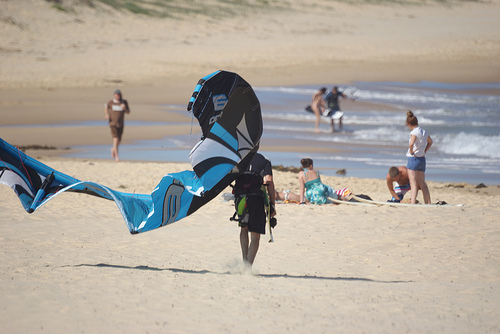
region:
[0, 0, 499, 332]
light sandy shore side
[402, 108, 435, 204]
woman with a bun hairstyle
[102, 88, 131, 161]
man jogging wearing all brown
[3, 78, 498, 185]
water coming into the shore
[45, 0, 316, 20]
grass patch on the sand dune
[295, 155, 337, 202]
woman wearing a green and white flowery dress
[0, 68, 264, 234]
large blue and black para sail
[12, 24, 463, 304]
this is on a beach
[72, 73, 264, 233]
this is a kite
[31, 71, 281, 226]
the kite is big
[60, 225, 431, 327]
this is a shadow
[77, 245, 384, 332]
the beach is sandy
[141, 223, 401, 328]
the man is walking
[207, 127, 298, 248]
the man is wearing black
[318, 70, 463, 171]
this is the ocean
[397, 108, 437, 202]
a cute girl on the beach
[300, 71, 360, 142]
a couple of people by the shore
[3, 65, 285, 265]
a man carries a large windsail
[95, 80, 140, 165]
a man in a brown shirt jogs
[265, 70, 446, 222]
people gather on a sandy beach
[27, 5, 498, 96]
big dunes above a shore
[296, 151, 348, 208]
a girl sitting on a towel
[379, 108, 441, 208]
a couple of people working on something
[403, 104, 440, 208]
a pretty woman in blue shorts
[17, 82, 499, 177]
ocean water on shore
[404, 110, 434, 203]
woman with hands on hips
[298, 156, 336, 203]
woman sitting on beach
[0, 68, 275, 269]
walking man carrying parasail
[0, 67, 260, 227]
blue and black design on nylon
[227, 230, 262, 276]
walking legs kicking up sand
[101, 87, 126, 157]
jogging person dressed in brown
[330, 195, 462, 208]
white surfboards on sand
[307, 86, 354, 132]
two people with board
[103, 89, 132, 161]
Man running on the beach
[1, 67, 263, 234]
Large blue, black and white kite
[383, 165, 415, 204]
Shirtless man kneeling in the sand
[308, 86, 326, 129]
Woman with a surfboard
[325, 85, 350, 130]
Man with a surfboard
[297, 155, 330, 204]
Woman in a green swimsuit sitting on the beach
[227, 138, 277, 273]
Man standing on the beach with a kite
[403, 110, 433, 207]
Woman watching a man dig in the sand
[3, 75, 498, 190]
Water from the ocean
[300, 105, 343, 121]
Surfboard held between two people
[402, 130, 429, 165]
the shirt is white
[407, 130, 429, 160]
the shirt is white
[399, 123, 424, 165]
the shirt is white